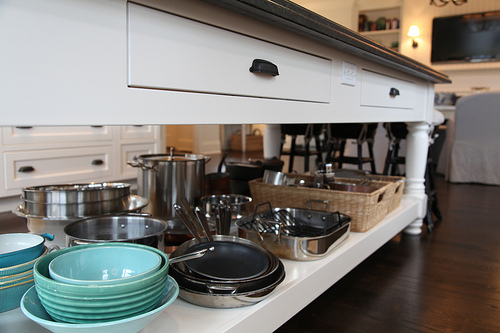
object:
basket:
[248, 172, 394, 232]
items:
[261, 156, 376, 192]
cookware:
[126, 153, 212, 246]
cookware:
[12, 194, 150, 249]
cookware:
[63, 213, 169, 249]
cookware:
[47, 246, 162, 286]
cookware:
[234, 199, 354, 262]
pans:
[183, 204, 269, 281]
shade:
[407, 25, 420, 36]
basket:
[230, 129, 262, 152]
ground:
[453, 158, 464, 170]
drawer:
[128, 0, 332, 104]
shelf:
[428, 62, 500, 119]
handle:
[389, 87, 400, 95]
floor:
[286, 171, 499, 332]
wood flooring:
[415, 255, 482, 315]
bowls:
[33, 242, 170, 324]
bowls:
[0, 232, 54, 269]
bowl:
[19, 274, 179, 333]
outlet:
[340, 60, 357, 87]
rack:
[239, 201, 348, 237]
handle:
[249, 201, 274, 216]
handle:
[321, 210, 341, 227]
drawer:
[360, 68, 417, 110]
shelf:
[0, 0, 452, 333]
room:
[0, 0, 499, 333]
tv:
[429, 10, 500, 65]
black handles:
[19, 166, 35, 173]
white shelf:
[0, 199, 419, 332]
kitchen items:
[1, 125, 405, 333]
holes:
[377, 192, 384, 203]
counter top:
[0, 0, 452, 333]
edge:
[213, 0, 452, 84]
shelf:
[350, 0, 400, 55]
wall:
[293, 1, 498, 101]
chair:
[449, 89, 499, 185]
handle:
[246, 54, 285, 81]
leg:
[403, 122, 429, 235]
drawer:
[3, 146, 111, 191]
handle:
[191, 204, 215, 247]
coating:
[191, 243, 262, 276]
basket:
[298, 171, 405, 214]